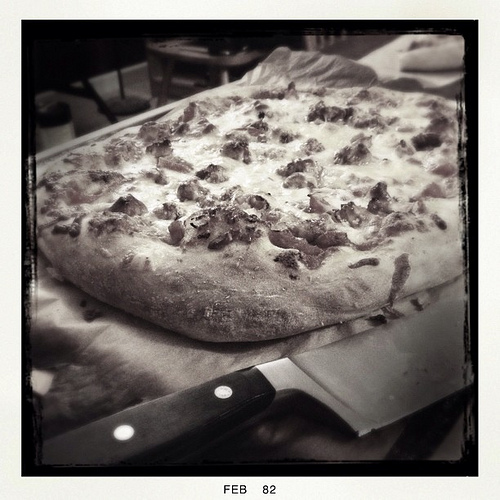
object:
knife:
[31, 285, 469, 480]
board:
[29, 49, 476, 478]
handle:
[30, 362, 275, 472]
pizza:
[26, 79, 469, 348]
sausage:
[270, 228, 318, 257]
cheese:
[234, 161, 277, 189]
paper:
[231, 43, 460, 99]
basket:
[32, 97, 77, 146]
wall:
[24, 22, 150, 90]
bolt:
[213, 385, 237, 399]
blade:
[278, 291, 475, 437]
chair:
[145, 34, 282, 116]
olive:
[411, 131, 442, 154]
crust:
[30, 221, 458, 348]